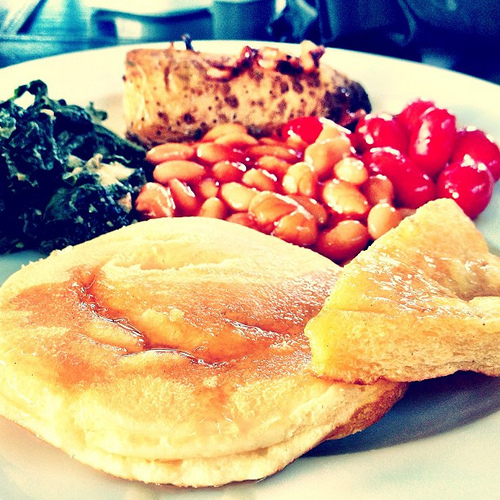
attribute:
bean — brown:
[326, 182, 372, 222]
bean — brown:
[318, 217, 374, 255]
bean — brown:
[217, 182, 264, 209]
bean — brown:
[246, 145, 301, 162]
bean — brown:
[138, 142, 200, 159]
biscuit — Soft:
[391, 250, 453, 337]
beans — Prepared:
[145, 92, 391, 247]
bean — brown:
[301, 137, 333, 175]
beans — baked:
[127, 109, 401, 270]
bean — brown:
[319, 182, 371, 216]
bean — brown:
[367, 202, 395, 249]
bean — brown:
[150, 157, 206, 183]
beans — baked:
[154, 115, 394, 255]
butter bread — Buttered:
[392, 200, 497, 312]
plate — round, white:
[5, 453, 489, 495]